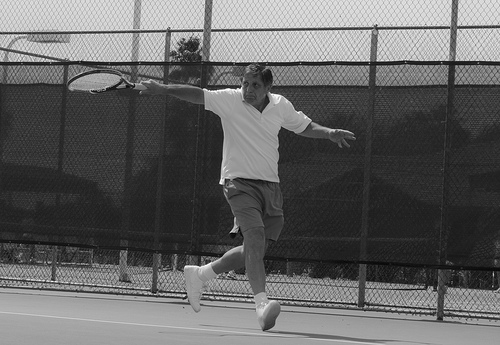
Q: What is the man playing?
A: Tennis.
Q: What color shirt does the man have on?
A: White.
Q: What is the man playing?
A: Tennis.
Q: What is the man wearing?
A: Shorts.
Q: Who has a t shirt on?
A: The man.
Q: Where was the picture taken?
A: On a tennis court.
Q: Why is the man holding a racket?
A: He is playing tennis.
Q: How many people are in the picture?
A: One.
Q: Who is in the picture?
A: A man.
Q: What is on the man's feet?
A: Tennis shoes.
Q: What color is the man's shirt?
A: White.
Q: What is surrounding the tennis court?
A: A fence.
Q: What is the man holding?
A: A racket.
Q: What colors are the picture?
A: Black and white.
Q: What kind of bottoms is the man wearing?
A: Shorts.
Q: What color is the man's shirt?
A: White.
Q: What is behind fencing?
A: Street light.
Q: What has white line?
A: Court.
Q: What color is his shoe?
A: White.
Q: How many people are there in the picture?
A: 1.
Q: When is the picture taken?
A: Daytime.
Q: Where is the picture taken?
A: Tennis court.